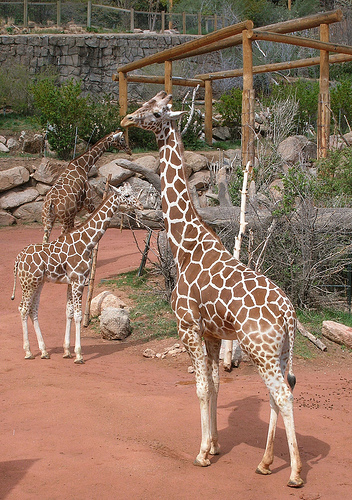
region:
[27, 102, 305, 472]
There are three giraffes in the picture.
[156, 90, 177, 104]
The horns on the giraffe.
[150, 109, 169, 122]
The right eye of the giraffe.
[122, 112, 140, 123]
The nose of the giraffe.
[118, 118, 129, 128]
The mouth of the giraffe.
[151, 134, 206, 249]
The neck of the giraffe.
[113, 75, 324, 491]
Giraffe is taller than the other giraffes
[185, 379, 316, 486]
The giraffe's legs are white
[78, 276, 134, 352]
Large rocks lay on the dirt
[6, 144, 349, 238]
Rocks are stacked into a wall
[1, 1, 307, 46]
A large wire and wood fence is seen in the back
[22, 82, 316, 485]
3 giraffes are hanging out in the zoo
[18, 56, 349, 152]
Bushes sit behind the giraffes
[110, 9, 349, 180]
wood poles are attached to each other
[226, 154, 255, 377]
A white tree is shot out from the ground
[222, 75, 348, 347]
several bushes have no leaves on them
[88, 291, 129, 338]
three boulders by the giraffes' feet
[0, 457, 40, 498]
a shadow on the ground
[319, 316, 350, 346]
a large rock on the grass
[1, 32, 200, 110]
a tall rock wall behind the giraffes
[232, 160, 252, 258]
a white piece of wood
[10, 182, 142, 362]
a small giraffe in the pen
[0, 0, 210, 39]
a fence at the top of the scene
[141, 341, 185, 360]
several small stones on the ground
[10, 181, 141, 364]
small giraffe in the pen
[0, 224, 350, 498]
pink substance on the ground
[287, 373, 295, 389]
a hairy tail of the giraffe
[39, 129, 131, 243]
a giraffe in the background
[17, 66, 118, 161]
a bush on the hillside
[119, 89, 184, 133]
the face of a giraffe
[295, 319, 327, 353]
a small log on the ground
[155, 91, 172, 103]
horns on the head of the giraffe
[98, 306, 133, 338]
rock on the ground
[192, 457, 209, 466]
the hoof of a giraffe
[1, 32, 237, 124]
gray stone wall behind giraffe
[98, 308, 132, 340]
large rock next to grass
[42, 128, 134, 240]
giraffe is standing in fornt of the rocks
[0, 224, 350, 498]
giraffe standing on a clay path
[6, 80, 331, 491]
The giraffes are in a pen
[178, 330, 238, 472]
front legs of a giraffe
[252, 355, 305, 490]
back legs of a giraffe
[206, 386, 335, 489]
the shadow of a giraffe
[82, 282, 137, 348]
the stones are small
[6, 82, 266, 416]
a baby giraffe near his mom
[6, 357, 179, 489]
the floor has dirt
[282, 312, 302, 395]
the tail has a turf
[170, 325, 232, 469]
The front legs of the prominent giraffe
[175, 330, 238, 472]
A set of front legs on the giraffe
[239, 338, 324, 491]
The back legs of the giraffe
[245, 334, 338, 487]
A set of back legs on the prominent giraffe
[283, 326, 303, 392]
The tail on the prominent giraffe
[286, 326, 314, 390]
A tail on the prominent giraffe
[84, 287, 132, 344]
The trio of rocks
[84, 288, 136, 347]
A trio of rocks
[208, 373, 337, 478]
The shadow of the prominent giraffe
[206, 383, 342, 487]
A shadow of the prominent giraffe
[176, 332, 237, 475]
The front legs on the prominent giraffe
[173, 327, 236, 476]
A set of front legs on the prominent giraffe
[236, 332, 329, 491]
The back legs on the prominent giraffe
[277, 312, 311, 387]
The tail on the prominent giraffe